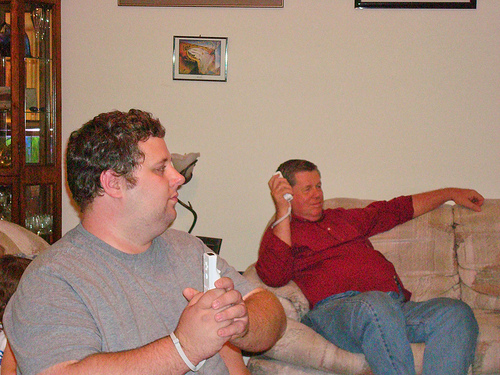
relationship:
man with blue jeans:
[257, 155, 499, 372] [304, 285, 479, 373]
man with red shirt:
[257, 155, 499, 372] [251, 193, 418, 308]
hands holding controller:
[176, 278, 255, 349] [196, 242, 222, 294]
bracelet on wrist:
[164, 328, 206, 372] [163, 330, 210, 373]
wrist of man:
[163, 330, 210, 373] [0, 106, 290, 373]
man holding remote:
[257, 155, 499, 372] [267, 170, 292, 230]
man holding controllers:
[0, 106, 290, 373] [199, 242, 226, 295]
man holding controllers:
[257, 155, 499, 372] [269, 165, 298, 210]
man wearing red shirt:
[257, 155, 499, 372] [254, 194, 415, 305]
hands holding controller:
[172, 274, 262, 364] [180, 237, 238, 321]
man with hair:
[16, 113, 327, 366] [60, 105, 173, 212]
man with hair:
[257, 155, 499, 372] [273, 151, 307, 188]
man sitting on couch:
[257, 155, 499, 372] [227, 191, 496, 369]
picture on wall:
[168, 32, 231, 84] [238, 18, 480, 161]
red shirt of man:
[254, 194, 415, 305] [257, 155, 499, 372]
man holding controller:
[257, 155, 499, 372] [270, 167, 293, 206]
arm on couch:
[326, 185, 483, 245] [227, 191, 496, 369]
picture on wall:
[168, 32, 231, 84] [61, 0, 498, 272]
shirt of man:
[2, 224, 259, 372] [0, 106, 290, 373]